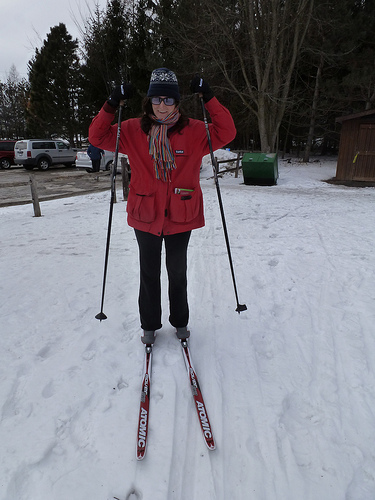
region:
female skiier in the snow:
[85, 51, 273, 467]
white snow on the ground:
[293, 276, 354, 478]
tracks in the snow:
[166, 399, 195, 486]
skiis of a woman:
[136, 346, 227, 460]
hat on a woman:
[144, 60, 179, 96]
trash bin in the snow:
[239, 145, 283, 195]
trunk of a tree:
[227, 14, 300, 151]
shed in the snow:
[315, 96, 370, 194]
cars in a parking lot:
[4, 131, 109, 185]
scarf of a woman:
[143, 112, 188, 183]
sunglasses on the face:
[138, 86, 172, 110]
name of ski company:
[186, 365, 219, 453]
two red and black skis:
[142, 350, 221, 488]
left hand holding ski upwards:
[194, 84, 264, 324]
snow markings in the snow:
[0, 344, 133, 499]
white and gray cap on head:
[149, 72, 190, 93]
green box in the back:
[241, 144, 282, 195]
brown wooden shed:
[341, 114, 373, 190]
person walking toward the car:
[85, 144, 98, 199]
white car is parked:
[18, 141, 68, 169]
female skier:
[78, 46, 253, 421]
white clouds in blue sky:
[10, 7, 32, 40]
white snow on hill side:
[268, 423, 303, 453]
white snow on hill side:
[309, 338, 346, 374]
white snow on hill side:
[278, 418, 327, 484]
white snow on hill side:
[298, 233, 341, 285]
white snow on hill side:
[41, 408, 87, 434]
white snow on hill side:
[48, 336, 87, 371]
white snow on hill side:
[18, 284, 54, 310]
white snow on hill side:
[42, 238, 102, 279]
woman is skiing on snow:
[90, 61, 287, 373]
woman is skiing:
[106, 69, 257, 334]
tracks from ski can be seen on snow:
[165, 443, 203, 498]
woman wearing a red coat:
[95, 102, 237, 237]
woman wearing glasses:
[146, 86, 180, 114]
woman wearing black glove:
[191, 63, 215, 103]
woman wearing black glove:
[105, 77, 126, 98]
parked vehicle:
[20, 132, 71, 166]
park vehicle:
[74, 141, 108, 170]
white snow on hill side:
[262, 248, 309, 284]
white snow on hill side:
[298, 303, 341, 361]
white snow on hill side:
[233, 400, 268, 445]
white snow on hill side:
[63, 375, 87, 396]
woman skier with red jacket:
[80, 58, 262, 393]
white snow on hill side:
[3, 366, 55, 404]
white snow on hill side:
[20, 433, 72, 491]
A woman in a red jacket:
[96, 102, 225, 362]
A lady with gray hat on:
[106, 59, 200, 147]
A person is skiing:
[78, 53, 261, 466]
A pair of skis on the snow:
[129, 336, 220, 462]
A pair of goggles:
[139, 82, 179, 112]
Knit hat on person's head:
[132, 57, 184, 124]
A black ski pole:
[187, 69, 255, 318]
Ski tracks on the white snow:
[0, 159, 366, 491]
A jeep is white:
[8, 130, 80, 173]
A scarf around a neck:
[135, 99, 188, 182]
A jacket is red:
[77, 94, 243, 244]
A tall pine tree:
[20, 15, 89, 141]